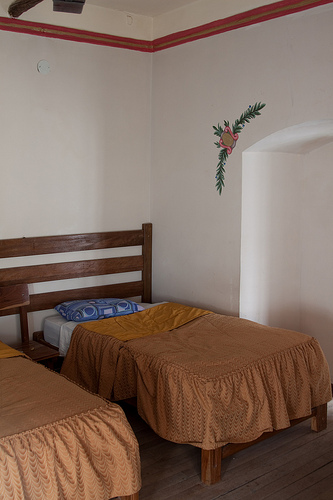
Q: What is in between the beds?
A: A chair.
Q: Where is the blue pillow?
A: On the right bed.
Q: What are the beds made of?
A: Wood.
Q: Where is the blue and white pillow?
A: On bed.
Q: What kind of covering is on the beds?
A: Orange comforter.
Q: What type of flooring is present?
A: Hardwood.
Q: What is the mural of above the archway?
A: A vase and ivy.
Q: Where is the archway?
A: Behind the bed on the right.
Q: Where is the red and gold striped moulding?
A: Near ceiling.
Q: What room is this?
A: Bedroom.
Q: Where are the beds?
A: Against wall.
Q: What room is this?
A: Bedroom.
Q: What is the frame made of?
A: Wood.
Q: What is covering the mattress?
A: Sheets.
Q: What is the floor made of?
A: Wood.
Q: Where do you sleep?
A: The bed.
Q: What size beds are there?
A: Twin bed.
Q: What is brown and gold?
A: Blanket.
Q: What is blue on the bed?
A: Pillow.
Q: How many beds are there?
A: 2.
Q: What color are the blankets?
A: Brown.